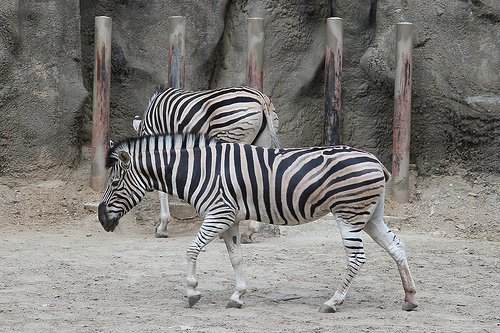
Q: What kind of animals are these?
A: Zebras.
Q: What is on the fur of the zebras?
A: Stripes.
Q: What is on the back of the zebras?
A: Mane.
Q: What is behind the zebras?
A: Large rock formation.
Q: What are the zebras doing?
A: Walking across the ground.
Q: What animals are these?
A: Zebras.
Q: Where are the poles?
A: Behind the zebras.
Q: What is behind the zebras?
A: Poles.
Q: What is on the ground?
A: Dirt.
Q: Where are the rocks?
A: Behind the posts.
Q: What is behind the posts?
A: Rocks.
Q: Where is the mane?
A: Zebra's back.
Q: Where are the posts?
A: Behind the zebras.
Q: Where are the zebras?
A: In front of the posts.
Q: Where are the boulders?
A: Behind the zebras.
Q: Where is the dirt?
A: Beneath the zebras.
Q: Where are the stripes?
A: On the zebras.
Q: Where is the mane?
A: Zebra's back.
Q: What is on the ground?
A: Dirt.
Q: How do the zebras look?
A: Black and white.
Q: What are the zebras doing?
A: Walking.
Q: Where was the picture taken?
A: At a zoo.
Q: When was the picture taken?
A: Daytime.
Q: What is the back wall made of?
A: Concrete.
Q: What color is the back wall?
A: Gray.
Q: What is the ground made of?
A: Dirt.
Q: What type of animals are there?
A: Zebras.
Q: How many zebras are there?
A: Two.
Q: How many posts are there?
A: Five.